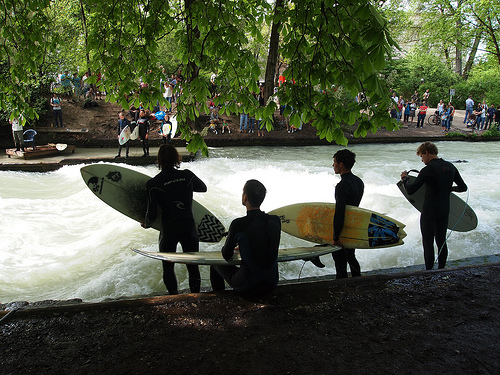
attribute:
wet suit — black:
[207, 209, 283, 294]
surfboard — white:
[255, 178, 414, 268]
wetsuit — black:
[135, 117, 151, 153]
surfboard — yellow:
[288, 201, 340, 246]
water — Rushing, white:
[0, 140, 499, 305]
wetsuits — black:
[138, 167, 206, 293]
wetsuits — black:
[211, 209, 280, 297]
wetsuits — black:
[327, 170, 365, 277]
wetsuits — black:
[399, 155, 464, 270]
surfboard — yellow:
[266, 198, 413, 253]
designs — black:
[87, 167, 120, 194]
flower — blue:
[369, 219, 401, 245]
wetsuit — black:
[146, 170, 204, 290]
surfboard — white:
[78, 162, 228, 244]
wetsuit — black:
[402, 158, 465, 278]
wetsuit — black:
[212, 210, 284, 308]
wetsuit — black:
[137, 166, 208, 290]